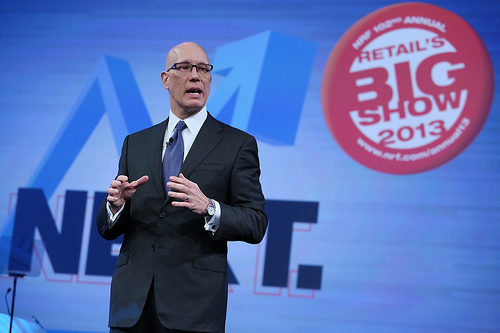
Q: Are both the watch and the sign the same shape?
A: Yes, both the watch and the sign are round.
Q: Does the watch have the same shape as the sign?
A: Yes, both the watch and the sign are round.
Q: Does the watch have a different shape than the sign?
A: No, both the watch and the sign are round.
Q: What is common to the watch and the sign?
A: The shape, both the watch and the sign are round.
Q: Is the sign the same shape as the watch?
A: Yes, both the sign and the watch are round.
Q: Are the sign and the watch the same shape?
A: Yes, both the sign and the watch are round.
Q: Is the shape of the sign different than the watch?
A: No, both the sign and the watch are round.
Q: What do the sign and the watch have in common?
A: The shape, both the sign and the watch are round.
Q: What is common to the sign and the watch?
A: The shape, both the sign and the watch are round.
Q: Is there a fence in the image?
A: No, there are no fences.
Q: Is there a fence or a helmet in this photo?
A: No, there are no fences or helmets.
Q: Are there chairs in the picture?
A: No, there are no chairs.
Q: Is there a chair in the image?
A: No, there are no chairs.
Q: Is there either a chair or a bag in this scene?
A: No, there are no chairs or bags.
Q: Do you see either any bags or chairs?
A: No, there are no chairs or bags.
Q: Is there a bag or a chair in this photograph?
A: No, there are no chairs or bags.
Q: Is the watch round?
A: Yes, the watch is round.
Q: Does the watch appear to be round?
A: Yes, the watch is round.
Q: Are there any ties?
A: Yes, there is a tie.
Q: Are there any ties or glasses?
A: Yes, there is a tie.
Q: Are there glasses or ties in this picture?
A: Yes, there is a tie.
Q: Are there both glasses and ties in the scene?
A: Yes, there are both a tie and glasses.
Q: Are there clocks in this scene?
A: No, there are no clocks.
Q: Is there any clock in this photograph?
A: No, there are no clocks.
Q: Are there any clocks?
A: No, there are no clocks.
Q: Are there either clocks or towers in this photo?
A: No, there are no clocks or towers.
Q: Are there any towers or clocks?
A: No, there are no clocks or towers.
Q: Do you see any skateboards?
A: No, there are no skateboards.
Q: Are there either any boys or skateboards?
A: No, there are no skateboards or boys.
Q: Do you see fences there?
A: No, there are no fences.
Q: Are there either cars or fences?
A: No, there are no fences or cars.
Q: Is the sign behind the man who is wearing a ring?
A: Yes, the sign is behind the man.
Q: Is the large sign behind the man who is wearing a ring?
A: Yes, the sign is behind the man.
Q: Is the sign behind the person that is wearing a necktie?
A: Yes, the sign is behind the man.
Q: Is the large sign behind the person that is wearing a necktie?
A: Yes, the sign is behind the man.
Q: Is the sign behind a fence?
A: No, the sign is behind the man.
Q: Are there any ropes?
A: No, there are no ropes.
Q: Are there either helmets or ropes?
A: No, there are no ropes or helmets.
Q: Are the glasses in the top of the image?
A: Yes, the glasses are in the top of the image.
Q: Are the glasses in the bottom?
A: No, the glasses are in the top of the image.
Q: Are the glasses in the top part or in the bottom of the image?
A: The glasses are in the top of the image.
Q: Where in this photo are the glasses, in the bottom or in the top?
A: The glasses are in the top of the image.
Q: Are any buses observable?
A: No, there are no buses.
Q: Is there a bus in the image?
A: No, there are no buses.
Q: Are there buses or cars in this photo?
A: No, there are no buses or cars.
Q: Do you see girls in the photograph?
A: No, there are no girls.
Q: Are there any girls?
A: No, there are no girls.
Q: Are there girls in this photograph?
A: No, there are no girls.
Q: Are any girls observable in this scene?
A: No, there are no girls.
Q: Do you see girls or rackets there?
A: No, there are no girls or rackets.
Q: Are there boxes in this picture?
A: No, there are no boxes.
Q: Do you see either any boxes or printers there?
A: No, there are no boxes or printers.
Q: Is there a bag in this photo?
A: No, there are no bags.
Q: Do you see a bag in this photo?
A: No, there are no bags.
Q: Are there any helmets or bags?
A: No, there are no bags or helmets.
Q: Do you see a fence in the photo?
A: No, there are no fences.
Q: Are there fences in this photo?
A: No, there are no fences.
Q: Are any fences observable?
A: No, there are no fences.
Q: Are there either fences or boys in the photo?
A: No, there are no fences or boys.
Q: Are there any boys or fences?
A: No, there are no fences or boys.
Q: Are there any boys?
A: No, there are no boys.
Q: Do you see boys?
A: No, there are no boys.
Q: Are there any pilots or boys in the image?
A: No, there are no boys or pilots.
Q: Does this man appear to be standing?
A: Yes, the man is standing.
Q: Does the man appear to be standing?
A: Yes, the man is standing.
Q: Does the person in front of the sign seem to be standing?
A: Yes, the man is standing.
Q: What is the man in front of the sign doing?
A: The man is standing.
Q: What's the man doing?
A: The man is standing.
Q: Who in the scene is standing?
A: The man is standing.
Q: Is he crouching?
A: No, the man is standing.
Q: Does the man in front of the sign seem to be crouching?
A: No, the man is standing.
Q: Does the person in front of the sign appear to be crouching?
A: No, the man is standing.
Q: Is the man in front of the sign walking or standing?
A: The man is standing.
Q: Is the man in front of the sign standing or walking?
A: The man is standing.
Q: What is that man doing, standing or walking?
A: The man is standing.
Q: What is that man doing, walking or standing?
A: The man is standing.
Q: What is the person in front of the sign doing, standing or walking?
A: The man is standing.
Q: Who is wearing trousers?
A: The man is wearing trousers.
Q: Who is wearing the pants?
A: The man is wearing trousers.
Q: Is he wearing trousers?
A: Yes, the man is wearing trousers.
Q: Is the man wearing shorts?
A: No, the man is wearing trousers.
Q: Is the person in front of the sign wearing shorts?
A: No, the man is wearing trousers.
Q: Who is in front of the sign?
A: The man is in front of the sign.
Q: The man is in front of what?
A: The man is in front of the sign.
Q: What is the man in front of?
A: The man is in front of the sign.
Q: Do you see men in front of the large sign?
A: Yes, there is a man in front of the sign.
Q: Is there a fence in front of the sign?
A: No, there is a man in front of the sign.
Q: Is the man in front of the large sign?
A: Yes, the man is in front of the sign.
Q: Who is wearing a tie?
A: The man is wearing a tie.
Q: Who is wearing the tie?
A: The man is wearing a tie.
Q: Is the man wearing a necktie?
A: Yes, the man is wearing a necktie.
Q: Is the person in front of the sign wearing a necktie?
A: Yes, the man is wearing a necktie.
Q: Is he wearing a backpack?
A: No, the man is wearing a necktie.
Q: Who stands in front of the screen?
A: The man stands in front of the screen.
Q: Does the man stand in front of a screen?
A: Yes, the man stands in front of a screen.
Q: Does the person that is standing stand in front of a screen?
A: Yes, the man stands in front of a screen.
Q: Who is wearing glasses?
A: The man is wearing glasses.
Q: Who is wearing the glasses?
A: The man is wearing glasses.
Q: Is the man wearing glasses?
A: Yes, the man is wearing glasses.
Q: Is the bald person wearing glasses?
A: Yes, the man is wearing glasses.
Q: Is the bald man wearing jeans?
A: No, the man is wearing glasses.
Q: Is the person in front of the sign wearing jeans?
A: No, the man is wearing glasses.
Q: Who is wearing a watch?
A: The man is wearing a watch.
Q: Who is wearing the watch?
A: The man is wearing a watch.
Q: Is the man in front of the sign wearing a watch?
A: Yes, the man is wearing a watch.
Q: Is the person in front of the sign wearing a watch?
A: Yes, the man is wearing a watch.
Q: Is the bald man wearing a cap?
A: No, the man is wearing a watch.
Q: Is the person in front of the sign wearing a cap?
A: No, the man is wearing a watch.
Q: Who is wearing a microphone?
A: The man is wearing a microphone.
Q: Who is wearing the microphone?
A: The man is wearing a microphone.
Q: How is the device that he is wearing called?
A: The device is a microphone.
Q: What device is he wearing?
A: The man is wearing a microphone.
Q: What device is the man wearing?
A: The man is wearing a microphone.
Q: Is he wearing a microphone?
A: Yes, the man is wearing a microphone.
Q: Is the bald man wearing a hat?
A: No, the man is wearing a microphone.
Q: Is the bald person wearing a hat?
A: No, the man is wearing a microphone.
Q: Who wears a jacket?
A: The man wears a jacket.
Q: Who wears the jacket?
A: The man wears a jacket.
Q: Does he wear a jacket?
A: Yes, the man wears a jacket.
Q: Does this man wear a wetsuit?
A: No, the man wears a jacket.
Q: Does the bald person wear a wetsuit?
A: No, the man wears a jacket.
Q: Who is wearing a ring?
A: The man is wearing a ring.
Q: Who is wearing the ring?
A: The man is wearing a ring.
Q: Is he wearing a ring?
A: Yes, the man is wearing a ring.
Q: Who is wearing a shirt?
A: The man is wearing a shirt.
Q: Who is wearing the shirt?
A: The man is wearing a shirt.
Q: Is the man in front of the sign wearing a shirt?
A: Yes, the man is wearing a shirt.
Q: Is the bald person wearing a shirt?
A: Yes, the man is wearing a shirt.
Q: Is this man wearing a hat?
A: No, the man is wearing a shirt.